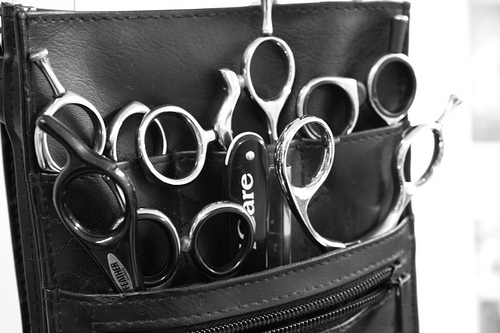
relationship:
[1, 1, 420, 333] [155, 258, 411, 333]
holder has a zipper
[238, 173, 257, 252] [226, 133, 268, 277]
text on object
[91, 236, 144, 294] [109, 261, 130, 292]
handle has text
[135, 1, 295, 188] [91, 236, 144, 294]
scissors are behind handle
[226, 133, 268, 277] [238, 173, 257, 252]
object has text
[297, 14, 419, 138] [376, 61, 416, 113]
scissors have a finger hole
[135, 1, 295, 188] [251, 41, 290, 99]
scissors have a finger hole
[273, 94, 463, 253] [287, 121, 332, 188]
scissors have a finger hole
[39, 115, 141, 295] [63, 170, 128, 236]
scissors have a finger hole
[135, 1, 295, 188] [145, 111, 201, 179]
scissors have a finger hole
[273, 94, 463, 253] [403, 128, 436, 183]
scissors have a finger hole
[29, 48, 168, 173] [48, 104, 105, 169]
scissors have a finger hole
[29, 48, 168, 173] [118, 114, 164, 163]
scissors have a finger hole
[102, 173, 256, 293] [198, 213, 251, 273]
scissors have a finger hole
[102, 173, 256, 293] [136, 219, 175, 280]
scissors have a finger hole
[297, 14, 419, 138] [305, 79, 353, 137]
scissors have a finger hole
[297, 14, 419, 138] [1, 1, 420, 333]
scissors are in holder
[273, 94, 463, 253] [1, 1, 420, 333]
scissors are in holder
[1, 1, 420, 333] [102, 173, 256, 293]
holder has scissors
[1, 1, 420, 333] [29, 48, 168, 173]
holder has scissors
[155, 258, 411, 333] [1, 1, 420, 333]
zipper on holder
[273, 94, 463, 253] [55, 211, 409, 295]
scissors are in slot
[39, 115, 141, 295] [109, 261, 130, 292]
scissors have text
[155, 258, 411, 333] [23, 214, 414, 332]
zipper on edge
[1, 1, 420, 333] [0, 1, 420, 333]
holder has holder